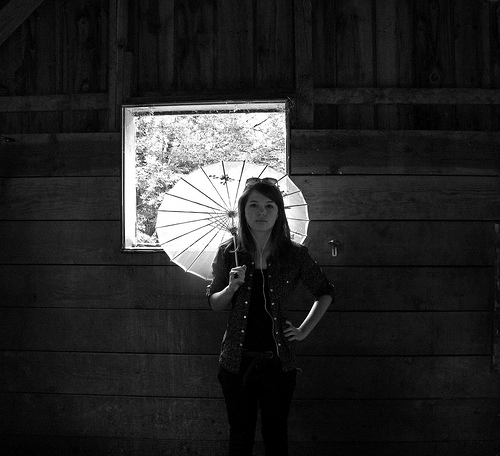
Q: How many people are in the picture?
A: One.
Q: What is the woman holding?
A: A parasol.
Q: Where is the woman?
A: In front of the window.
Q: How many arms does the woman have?
A: Two.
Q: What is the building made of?
A: Wood.